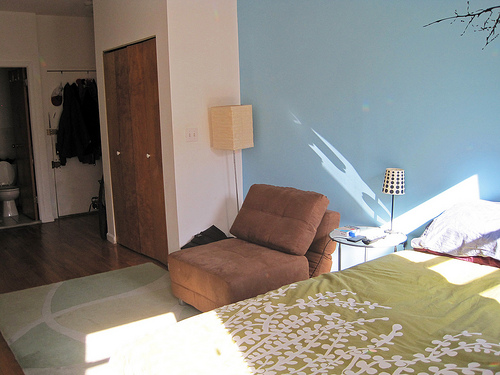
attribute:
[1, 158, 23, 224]
toilet — white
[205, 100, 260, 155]
shade — beige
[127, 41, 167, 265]
door — brown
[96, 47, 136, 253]
door — brown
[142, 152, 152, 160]
knob — white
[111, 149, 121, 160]
knob — white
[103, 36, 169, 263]
doors — wood, closet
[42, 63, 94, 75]
bar — metal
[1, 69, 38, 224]
bathroom — open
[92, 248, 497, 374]
bedspread — green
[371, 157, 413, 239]
lamp — small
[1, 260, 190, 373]
rug — green, yellow, area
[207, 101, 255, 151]
shade — square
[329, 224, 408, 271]
table — round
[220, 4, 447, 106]
wall — light blue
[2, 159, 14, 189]
lid — open